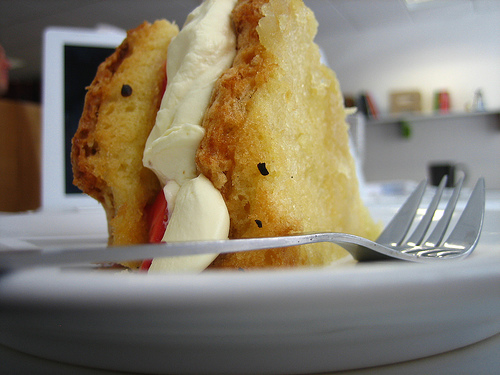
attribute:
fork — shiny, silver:
[0, 175, 486, 294]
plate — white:
[1, 199, 500, 375]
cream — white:
[142, 0, 237, 275]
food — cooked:
[70, 0, 385, 270]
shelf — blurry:
[365, 109, 500, 124]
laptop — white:
[43, 28, 127, 234]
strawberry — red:
[139, 187, 169, 271]